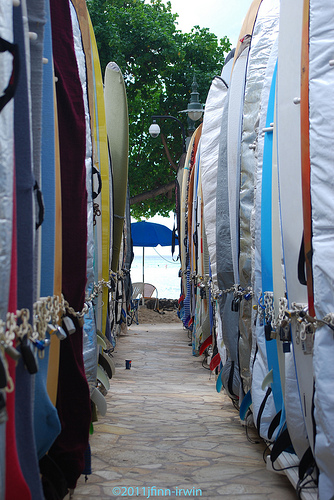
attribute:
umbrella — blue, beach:
[130, 220, 177, 247]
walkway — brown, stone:
[105, 325, 207, 482]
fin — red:
[208, 350, 221, 373]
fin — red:
[196, 335, 211, 355]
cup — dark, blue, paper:
[122, 355, 131, 370]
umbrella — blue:
[130, 216, 179, 301]